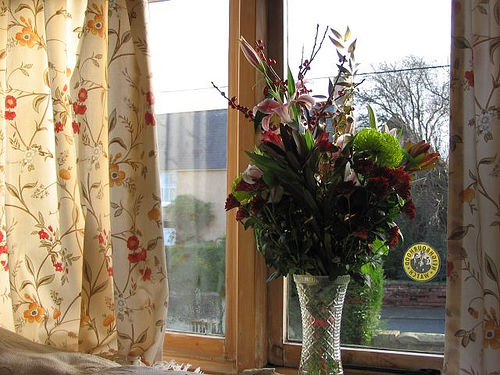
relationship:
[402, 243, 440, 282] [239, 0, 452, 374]
sticker on window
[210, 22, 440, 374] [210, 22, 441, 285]
flowers are in an arrangement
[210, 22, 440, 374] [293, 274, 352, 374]
flowers are in a vase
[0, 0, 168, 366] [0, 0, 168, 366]
curtains have a curtains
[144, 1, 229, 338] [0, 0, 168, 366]
window has curtains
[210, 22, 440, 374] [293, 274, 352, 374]
plant in a vase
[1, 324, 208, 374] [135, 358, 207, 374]
blanket has white frill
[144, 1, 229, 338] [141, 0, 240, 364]
window has a seal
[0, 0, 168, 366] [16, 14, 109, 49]
curtains have sunflowers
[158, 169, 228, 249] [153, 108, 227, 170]
building has a black roof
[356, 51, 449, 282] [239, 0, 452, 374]
tree outside window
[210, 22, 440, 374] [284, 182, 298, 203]
plant has part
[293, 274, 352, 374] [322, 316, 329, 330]
vase has part